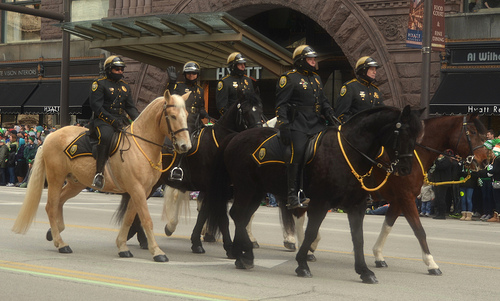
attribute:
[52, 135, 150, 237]
horse — beige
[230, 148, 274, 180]
horse — black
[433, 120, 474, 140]
horse — brown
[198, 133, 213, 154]
horse — black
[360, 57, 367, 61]
helmet — gold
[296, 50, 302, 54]
helmet — gold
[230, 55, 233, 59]
helmet — gold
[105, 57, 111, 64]
helmet — gold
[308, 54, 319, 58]
visor — black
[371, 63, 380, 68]
visor — black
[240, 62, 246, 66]
visor — black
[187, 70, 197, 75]
visor — black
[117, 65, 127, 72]
visor — black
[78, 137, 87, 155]
saddle — black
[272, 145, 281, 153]
saddle — black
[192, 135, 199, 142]
saddle — black